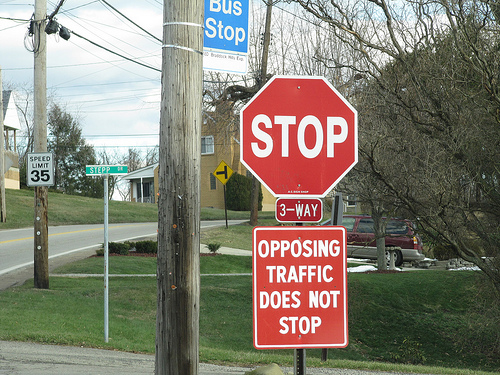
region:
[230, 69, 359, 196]
White and red traffic sin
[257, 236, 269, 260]
White lettering on red sign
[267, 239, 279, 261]
White lettering on red sign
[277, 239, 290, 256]
White lettering on red sign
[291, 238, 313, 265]
White lettering on red sign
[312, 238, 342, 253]
White lettering on red sign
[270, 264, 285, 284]
White lettering on red sign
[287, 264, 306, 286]
White lettering on red sign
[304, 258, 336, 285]
White lettering on red sign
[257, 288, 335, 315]
White lettering on red sign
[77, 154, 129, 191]
street sign on pole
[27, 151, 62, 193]
street sign on pole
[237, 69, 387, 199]
street sign on pole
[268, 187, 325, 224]
street sign on pole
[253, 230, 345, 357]
street sign on pole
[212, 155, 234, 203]
street sign on pole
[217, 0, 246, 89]
street sign on pole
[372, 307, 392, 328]
patch of green grass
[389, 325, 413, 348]
patch of green grass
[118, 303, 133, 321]
patch of green grass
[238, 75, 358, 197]
a red stop sign with white letters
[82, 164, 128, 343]
a green street sign with a silver pole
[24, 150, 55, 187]
a speed limit sign hanging on a wooden pole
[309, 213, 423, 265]
a maroon and tan minivan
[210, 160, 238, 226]
a yellow street sign on a black pole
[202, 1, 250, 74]
a blue and white bus stop sign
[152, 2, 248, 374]
a blue and white sign attached to a pole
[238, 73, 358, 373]
three signs attached to one pole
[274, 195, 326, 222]
a red 3-way traffic sign with white letters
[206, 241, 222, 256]
a small green shrub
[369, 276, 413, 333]
the grass is short and dark green.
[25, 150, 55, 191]
a sign with speed limit 35.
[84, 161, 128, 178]
a green street sign says stepp rd.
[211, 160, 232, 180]
a yellow and black street sign.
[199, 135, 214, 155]
a huge white window.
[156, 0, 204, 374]
a huge thick tree pole.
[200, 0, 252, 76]
a blue and white sign says bus stop.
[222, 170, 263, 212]
two huge green bushes.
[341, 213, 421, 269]
a burgundy and grey truck is parked.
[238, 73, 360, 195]
a red and white stop sign.